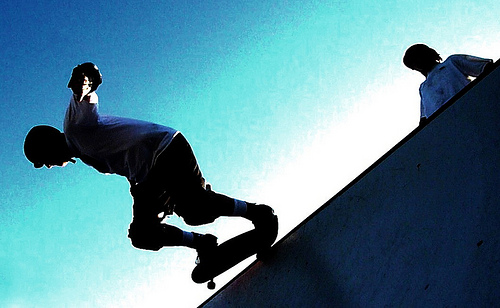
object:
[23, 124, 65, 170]
helmet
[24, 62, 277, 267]
man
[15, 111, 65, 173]
helmet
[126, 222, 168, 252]
kneepad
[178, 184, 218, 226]
kneepad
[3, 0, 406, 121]
sky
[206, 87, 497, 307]
ramp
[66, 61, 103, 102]
pad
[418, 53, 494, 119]
shirt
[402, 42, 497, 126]
man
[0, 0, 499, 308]
cloud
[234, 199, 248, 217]
sock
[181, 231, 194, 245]
sock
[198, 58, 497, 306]
halfpipe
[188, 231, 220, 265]
skates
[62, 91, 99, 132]
short sleeves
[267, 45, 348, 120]
bright blue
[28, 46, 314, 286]
skateboarder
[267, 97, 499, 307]
wall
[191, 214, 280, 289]
board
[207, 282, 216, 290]
wheel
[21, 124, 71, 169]
head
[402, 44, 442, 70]
hat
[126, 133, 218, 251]
shorts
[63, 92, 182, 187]
shirt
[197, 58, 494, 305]
edge